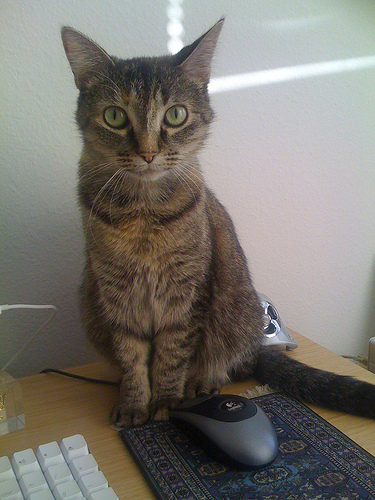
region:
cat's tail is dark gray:
[258, 340, 372, 422]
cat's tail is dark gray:
[259, 305, 330, 408]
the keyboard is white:
[5, 429, 121, 497]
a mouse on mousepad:
[159, 383, 267, 468]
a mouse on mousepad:
[149, 366, 333, 497]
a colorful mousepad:
[114, 391, 373, 498]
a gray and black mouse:
[166, 390, 278, 476]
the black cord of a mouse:
[40, 363, 121, 389]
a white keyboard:
[1, 432, 119, 499]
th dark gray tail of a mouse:
[256, 347, 372, 419]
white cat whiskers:
[79, 156, 129, 231]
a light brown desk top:
[0, 323, 373, 499]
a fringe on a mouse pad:
[234, 381, 276, 400]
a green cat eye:
[102, 100, 126, 129]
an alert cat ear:
[179, 15, 229, 89]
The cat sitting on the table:
[26, 5, 304, 480]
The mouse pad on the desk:
[117, 380, 372, 498]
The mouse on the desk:
[172, 392, 280, 467]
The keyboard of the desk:
[4, 433, 125, 496]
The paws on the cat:
[104, 395, 185, 431]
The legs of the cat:
[99, 265, 201, 388]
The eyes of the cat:
[98, 95, 192, 133]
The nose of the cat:
[133, 145, 162, 165]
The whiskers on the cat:
[69, 155, 222, 232]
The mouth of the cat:
[121, 159, 172, 187]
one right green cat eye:
[99, 103, 130, 131]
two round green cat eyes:
[94, 98, 189, 132]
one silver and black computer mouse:
[167, 386, 283, 476]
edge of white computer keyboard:
[5, 431, 120, 497]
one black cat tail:
[256, 347, 372, 410]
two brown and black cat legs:
[110, 330, 190, 429]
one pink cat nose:
[138, 150, 158, 168]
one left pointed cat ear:
[177, 7, 232, 85]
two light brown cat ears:
[52, 14, 229, 85]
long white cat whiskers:
[79, 154, 216, 227]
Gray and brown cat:
[62, 17, 270, 426]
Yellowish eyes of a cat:
[101, 92, 188, 133]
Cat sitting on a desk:
[58, 15, 262, 425]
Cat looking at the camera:
[52, 15, 262, 427]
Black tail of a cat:
[261, 349, 372, 413]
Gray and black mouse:
[176, 377, 275, 462]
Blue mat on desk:
[118, 383, 373, 493]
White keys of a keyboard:
[1, 435, 101, 497]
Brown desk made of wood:
[0, 330, 370, 492]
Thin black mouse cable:
[44, 365, 176, 405]